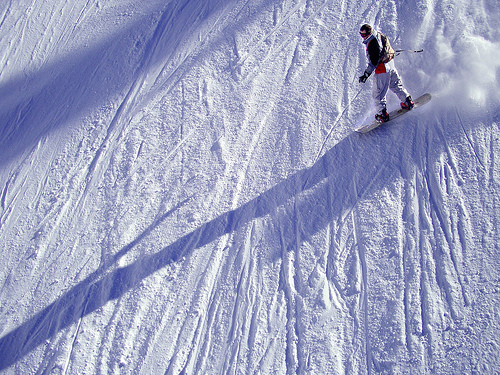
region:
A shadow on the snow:
[6, 125, 381, 363]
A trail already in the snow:
[166, 173, 452, 373]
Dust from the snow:
[411, 34, 498, 110]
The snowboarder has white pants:
[370, 70, 412, 108]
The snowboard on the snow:
[353, 94, 433, 134]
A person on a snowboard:
[353, 27, 415, 123]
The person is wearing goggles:
[359, 30, 370, 40]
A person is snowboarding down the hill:
[350, 24, 433, 134]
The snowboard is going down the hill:
[355, 90, 431, 131]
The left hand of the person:
[355, 73, 367, 85]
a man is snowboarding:
[303, 15, 465, 162]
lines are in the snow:
[326, 139, 461, 334]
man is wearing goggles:
[337, 6, 376, 41]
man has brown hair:
[349, 12, 379, 38]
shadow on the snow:
[55, 158, 377, 303]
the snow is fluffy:
[407, 34, 489, 137]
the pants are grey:
[352, 67, 415, 106]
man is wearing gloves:
[335, 66, 390, 98]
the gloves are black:
[344, 61, 372, 89]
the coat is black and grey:
[322, 11, 443, 88]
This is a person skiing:
[346, 14, 448, 145]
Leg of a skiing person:
[369, 72, 391, 131]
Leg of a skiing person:
[386, 63, 421, 116]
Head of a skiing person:
[356, 16, 376, 38]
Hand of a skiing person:
[357, 45, 374, 85]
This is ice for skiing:
[220, 209, 360, 334]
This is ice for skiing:
[399, 275, 481, 371]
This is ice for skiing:
[61, 269, 177, 371]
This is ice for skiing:
[163, 120, 280, 280]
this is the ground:
[57, 30, 187, 141]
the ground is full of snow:
[45, 215, 200, 350]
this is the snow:
[53, 197, 193, 321]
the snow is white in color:
[21, 205, 106, 273]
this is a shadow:
[109, 228, 151, 305]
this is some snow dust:
[427, 12, 488, 102]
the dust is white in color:
[451, 32, 498, 109]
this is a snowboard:
[346, 90, 446, 129]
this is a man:
[357, 18, 408, 116]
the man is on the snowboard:
[351, 13, 421, 120]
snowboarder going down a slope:
[349, 24, 433, 137]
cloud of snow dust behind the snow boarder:
[422, 36, 494, 116]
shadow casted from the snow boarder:
[4, 114, 381, 366]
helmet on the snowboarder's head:
[355, 19, 380, 34]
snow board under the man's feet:
[358, 91, 433, 133]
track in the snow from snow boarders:
[275, 0, 314, 372]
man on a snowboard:
[350, 20, 435, 148]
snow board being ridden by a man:
[358, 87, 430, 133]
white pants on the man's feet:
[369, 66, 411, 108]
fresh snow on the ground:
[6, 0, 498, 373]